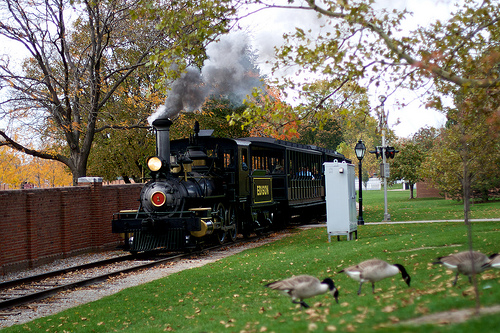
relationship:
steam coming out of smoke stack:
[148, 30, 278, 122] [148, 117, 178, 168]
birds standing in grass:
[261, 273, 339, 309] [0, 222, 498, 330]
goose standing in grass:
[337, 255, 413, 294] [0, 222, 498, 330]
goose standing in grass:
[432, 242, 499, 287] [0, 222, 498, 330]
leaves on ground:
[372, 282, 444, 310] [144, 292, 234, 332]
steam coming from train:
[148, 30, 278, 122] [112, 117, 352, 252]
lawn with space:
[240, 230, 472, 327] [258, 229, 450, 272]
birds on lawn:
[256, 246, 416, 319] [193, 215, 491, 329]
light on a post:
[349, 137, 386, 162] [331, 152, 392, 202]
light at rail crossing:
[353, 139, 367, 164] [356, 102, 497, 238]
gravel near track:
[119, 273, 140, 283] [185, 243, 465, 331]